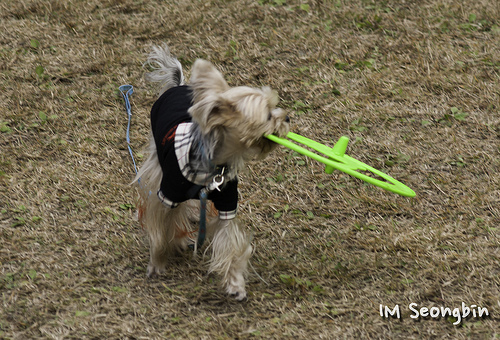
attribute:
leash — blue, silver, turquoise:
[118, 84, 224, 253]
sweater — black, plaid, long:
[149, 84, 238, 220]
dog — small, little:
[129, 40, 292, 300]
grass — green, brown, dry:
[1, 1, 499, 339]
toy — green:
[265, 128, 418, 200]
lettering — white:
[379, 301, 488, 326]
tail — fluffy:
[146, 40, 183, 90]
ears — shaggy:
[188, 97, 239, 136]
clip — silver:
[210, 166, 226, 195]